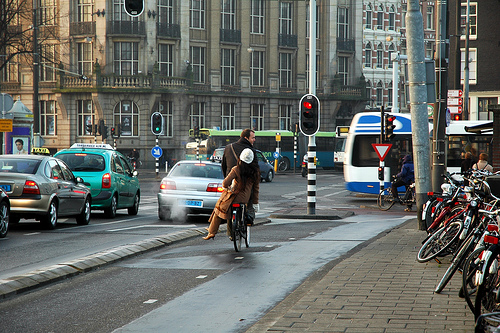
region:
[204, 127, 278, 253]
man and woman on a bike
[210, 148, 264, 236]
lady wearing a white hat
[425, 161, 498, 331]
a row of bicycles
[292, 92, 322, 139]
a red stop light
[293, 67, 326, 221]
black and white pole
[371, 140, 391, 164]
red and white triangle sign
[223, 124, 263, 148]
man looking behind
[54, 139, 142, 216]
green taxi cab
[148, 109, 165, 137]
green stop light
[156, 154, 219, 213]
a car blow white smoke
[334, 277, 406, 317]
a brick side walk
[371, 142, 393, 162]
a red and white yeild sign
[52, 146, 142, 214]
a green van in the street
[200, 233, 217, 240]
a brown shoe with heel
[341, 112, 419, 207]
a blue and white bus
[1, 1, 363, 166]
a large building in the background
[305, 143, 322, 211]
a black and white stripped pole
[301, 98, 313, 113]
a red light stopping traffic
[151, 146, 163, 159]
a round blue sign with an arrow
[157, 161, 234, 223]
a silver car driving down the street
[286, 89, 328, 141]
a red stoplight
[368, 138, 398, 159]
a red and white yield symbol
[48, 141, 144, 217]
a blue sport utility vehicle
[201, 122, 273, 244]
a man and a woman on a bike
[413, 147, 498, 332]
bicycles parked outside of a shop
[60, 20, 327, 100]
a strip of windows on the building off the street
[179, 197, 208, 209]
a blue license plate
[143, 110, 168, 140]
a green traffic light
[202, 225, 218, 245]
brown high heels on the woman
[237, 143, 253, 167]
the woman is wearing a white hat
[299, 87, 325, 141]
a red stop light in middle of road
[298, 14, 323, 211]
a black and white pole with stop light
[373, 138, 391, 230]
a yield sign on side of road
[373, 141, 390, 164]
a red and white triangle yield sign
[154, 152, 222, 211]
a white car stopped at stop light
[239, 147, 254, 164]
a person wearing a white helmet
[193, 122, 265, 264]
two people on a bike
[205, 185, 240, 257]
girl on bike wearing a dress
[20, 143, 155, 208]
a green van parked on side of road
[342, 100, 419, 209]
a blue and white bus parked next to sidewalk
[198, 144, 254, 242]
Woman wearing white beanie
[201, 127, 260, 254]
Man riding bicycle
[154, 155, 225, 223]
Silver car next to teal car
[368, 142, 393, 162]
Triangular red and white sign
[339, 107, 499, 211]
Blue and white bus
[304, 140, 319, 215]
Striped black and white light post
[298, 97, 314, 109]
Light is red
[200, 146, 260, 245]
Woman wearing long brown coat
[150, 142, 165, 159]
Round blue sign with white arrow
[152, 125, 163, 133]
Light above white arrow is green